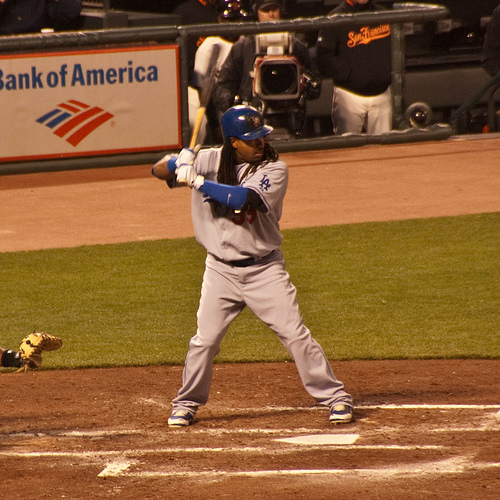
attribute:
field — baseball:
[4, 129, 492, 496]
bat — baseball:
[187, 103, 208, 155]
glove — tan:
[16, 329, 62, 372]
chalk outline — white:
[2, 397, 499, 477]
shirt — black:
[313, 1, 392, 95]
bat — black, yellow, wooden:
[186, 39, 224, 153]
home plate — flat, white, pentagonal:
[270, 432, 362, 452]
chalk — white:
[383, 385, 460, 424]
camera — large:
[231, 21, 340, 133]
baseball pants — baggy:
[166, 252, 358, 410]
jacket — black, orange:
[315, 2, 390, 95]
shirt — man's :
[168, 140, 302, 269]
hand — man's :
[173, 141, 209, 194]